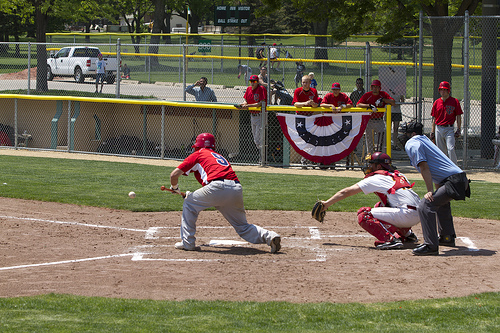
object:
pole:
[27, 40, 31, 98]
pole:
[115, 36, 120, 98]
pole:
[183, 43, 186, 102]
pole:
[266, 41, 271, 104]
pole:
[415, 23, 424, 132]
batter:
[169, 131, 284, 256]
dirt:
[0, 194, 499, 310]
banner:
[274, 112, 373, 166]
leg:
[228, 181, 282, 253]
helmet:
[194, 133, 216, 149]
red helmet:
[368, 152, 394, 172]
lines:
[131, 223, 326, 262]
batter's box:
[131, 222, 326, 263]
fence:
[1, 5, 500, 168]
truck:
[46, 42, 123, 85]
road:
[1, 69, 498, 134]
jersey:
[176, 148, 240, 184]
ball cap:
[331, 82, 341, 89]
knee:
[236, 224, 250, 234]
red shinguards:
[358, 207, 392, 241]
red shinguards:
[374, 201, 383, 208]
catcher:
[317, 152, 424, 250]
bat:
[160, 186, 187, 197]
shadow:
[442, 243, 497, 257]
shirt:
[356, 169, 423, 210]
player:
[243, 75, 269, 164]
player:
[294, 76, 320, 168]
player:
[429, 80, 461, 174]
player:
[360, 78, 397, 166]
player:
[322, 81, 352, 112]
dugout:
[4, 89, 391, 172]